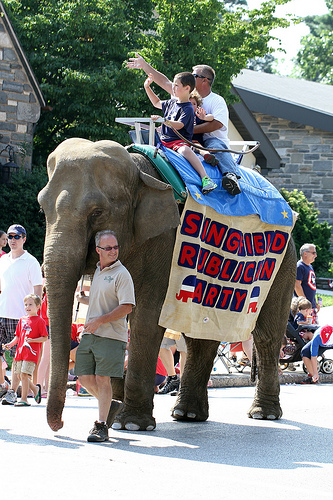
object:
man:
[74, 227, 137, 443]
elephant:
[37, 138, 298, 431]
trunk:
[42, 214, 90, 432]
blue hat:
[7, 224, 27, 237]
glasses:
[97, 244, 120, 252]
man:
[294, 241, 320, 326]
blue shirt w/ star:
[293, 260, 317, 309]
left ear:
[130, 168, 181, 248]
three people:
[126, 52, 243, 194]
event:
[0, 51, 333, 498]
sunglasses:
[6, 234, 22, 241]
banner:
[157, 192, 299, 344]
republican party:
[174, 241, 276, 314]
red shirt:
[14, 314, 49, 364]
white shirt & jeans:
[197, 90, 243, 178]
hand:
[143, 72, 155, 88]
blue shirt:
[159, 99, 194, 141]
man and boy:
[0, 223, 49, 407]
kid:
[293, 300, 315, 341]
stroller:
[278, 309, 333, 373]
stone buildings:
[0, 0, 333, 289]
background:
[1, 0, 333, 498]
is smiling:
[107, 250, 119, 260]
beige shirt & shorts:
[72, 258, 137, 378]